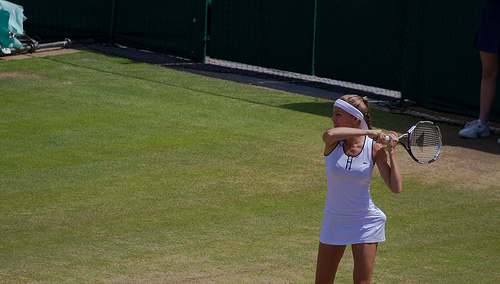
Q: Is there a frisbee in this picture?
A: No, there are no frisbees.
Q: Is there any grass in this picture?
A: Yes, there is grass.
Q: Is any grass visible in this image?
A: Yes, there is grass.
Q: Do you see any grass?
A: Yes, there is grass.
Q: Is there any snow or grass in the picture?
A: Yes, there is grass.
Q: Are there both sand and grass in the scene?
A: No, there is grass but no sand.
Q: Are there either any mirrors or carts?
A: No, there are no carts or mirrors.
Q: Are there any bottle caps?
A: No, there are no bottle caps.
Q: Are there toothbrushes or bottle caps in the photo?
A: No, there are no bottle caps or toothbrushes.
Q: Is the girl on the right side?
A: Yes, the girl is on the right of the image.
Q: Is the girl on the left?
A: No, the girl is on the right of the image.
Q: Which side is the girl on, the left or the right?
A: The girl is on the right of the image.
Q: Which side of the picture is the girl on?
A: The girl is on the right of the image.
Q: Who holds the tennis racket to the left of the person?
A: The girl holds the tennis racket.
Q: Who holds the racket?
A: The girl holds the tennis racket.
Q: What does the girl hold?
A: The girl holds the racket.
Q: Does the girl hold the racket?
A: Yes, the girl holds the racket.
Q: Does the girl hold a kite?
A: No, the girl holds the racket.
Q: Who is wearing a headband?
A: The girl is wearing a headband.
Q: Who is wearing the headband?
A: The girl is wearing a headband.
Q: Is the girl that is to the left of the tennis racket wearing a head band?
A: Yes, the girl is wearing a head band.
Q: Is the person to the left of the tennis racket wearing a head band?
A: Yes, the girl is wearing a head band.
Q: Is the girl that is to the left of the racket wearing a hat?
A: No, the girl is wearing a head band.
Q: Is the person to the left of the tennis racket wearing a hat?
A: No, the girl is wearing a head band.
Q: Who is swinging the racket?
A: The girl is swinging the racket.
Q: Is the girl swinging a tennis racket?
A: Yes, the girl is swinging a tennis racket.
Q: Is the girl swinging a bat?
A: No, the girl is swinging a tennis racket.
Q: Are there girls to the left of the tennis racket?
A: Yes, there is a girl to the left of the tennis racket.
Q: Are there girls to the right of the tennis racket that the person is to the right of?
A: No, the girl is to the left of the tennis racket.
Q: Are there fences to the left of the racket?
A: No, there is a girl to the left of the racket.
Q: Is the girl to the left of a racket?
A: Yes, the girl is to the left of a racket.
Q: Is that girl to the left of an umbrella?
A: No, the girl is to the left of a racket.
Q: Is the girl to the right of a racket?
A: No, the girl is to the left of a racket.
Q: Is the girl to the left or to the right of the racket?
A: The girl is to the left of the racket.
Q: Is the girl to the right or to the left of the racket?
A: The girl is to the left of the racket.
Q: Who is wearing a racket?
A: The girl is wearing a racket.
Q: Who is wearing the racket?
A: The girl is wearing a racket.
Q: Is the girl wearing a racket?
A: Yes, the girl is wearing a racket.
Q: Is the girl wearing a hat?
A: No, the girl is wearing a racket.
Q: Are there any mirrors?
A: No, there are no mirrors.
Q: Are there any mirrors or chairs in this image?
A: No, there are no mirrors or chairs.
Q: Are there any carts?
A: No, there are no carts.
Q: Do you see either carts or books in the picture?
A: No, there are no carts or books.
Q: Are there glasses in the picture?
A: No, there are no glasses.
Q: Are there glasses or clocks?
A: No, there are no glasses or clocks.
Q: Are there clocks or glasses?
A: No, there are no glasses or clocks.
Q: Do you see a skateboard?
A: No, there are no skateboards.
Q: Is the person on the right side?
A: Yes, the person is on the right of the image.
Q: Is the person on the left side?
A: No, the person is on the right of the image.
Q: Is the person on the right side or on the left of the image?
A: The person is on the right of the image.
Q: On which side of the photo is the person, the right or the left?
A: The person is on the right of the image.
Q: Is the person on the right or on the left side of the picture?
A: The person is on the right of the image.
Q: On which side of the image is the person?
A: The person is on the right of the image.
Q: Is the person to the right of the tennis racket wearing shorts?
A: Yes, the person is wearing shorts.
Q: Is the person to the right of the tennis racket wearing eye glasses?
A: No, the person is wearing shorts.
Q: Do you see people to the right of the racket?
A: Yes, there is a person to the right of the racket.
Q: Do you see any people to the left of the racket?
A: No, the person is to the right of the racket.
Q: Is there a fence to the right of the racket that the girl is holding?
A: No, there is a person to the right of the racket.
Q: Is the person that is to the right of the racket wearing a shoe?
A: Yes, the person is wearing a shoe.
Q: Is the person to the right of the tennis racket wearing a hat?
A: No, the person is wearing a shoe.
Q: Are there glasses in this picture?
A: No, there are no glasses.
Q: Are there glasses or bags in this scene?
A: No, there are no glasses or bags.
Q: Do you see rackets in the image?
A: Yes, there is a racket.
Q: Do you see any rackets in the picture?
A: Yes, there is a racket.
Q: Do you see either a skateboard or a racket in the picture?
A: Yes, there is a racket.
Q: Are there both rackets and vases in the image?
A: No, there is a racket but no vases.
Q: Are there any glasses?
A: No, there are no glasses.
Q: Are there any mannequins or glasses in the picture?
A: No, there are no glasses or mannequins.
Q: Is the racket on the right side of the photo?
A: Yes, the racket is on the right of the image.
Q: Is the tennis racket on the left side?
A: No, the tennis racket is on the right of the image.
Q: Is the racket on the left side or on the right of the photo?
A: The racket is on the right of the image.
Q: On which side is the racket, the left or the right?
A: The racket is on the right of the image.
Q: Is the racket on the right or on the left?
A: The racket is on the right of the image.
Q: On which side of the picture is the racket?
A: The racket is on the right of the image.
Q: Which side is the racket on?
A: The racket is on the right of the image.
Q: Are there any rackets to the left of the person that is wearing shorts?
A: Yes, there is a racket to the left of the person.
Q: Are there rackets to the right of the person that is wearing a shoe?
A: No, the racket is to the left of the person.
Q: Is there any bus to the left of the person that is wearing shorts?
A: No, there is a racket to the left of the person.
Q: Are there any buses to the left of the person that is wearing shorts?
A: No, there is a racket to the left of the person.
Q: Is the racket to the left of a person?
A: Yes, the racket is to the left of a person.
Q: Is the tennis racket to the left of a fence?
A: No, the tennis racket is to the left of a person.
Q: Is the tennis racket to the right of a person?
A: No, the tennis racket is to the left of a person.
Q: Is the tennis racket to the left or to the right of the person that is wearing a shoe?
A: The tennis racket is to the left of the person.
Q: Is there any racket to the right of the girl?
A: Yes, there is a racket to the right of the girl.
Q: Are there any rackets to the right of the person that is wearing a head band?
A: Yes, there is a racket to the right of the girl.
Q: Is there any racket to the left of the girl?
A: No, the racket is to the right of the girl.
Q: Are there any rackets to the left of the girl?
A: No, the racket is to the right of the girl.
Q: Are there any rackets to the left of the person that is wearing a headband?
A: No, the racket is to the right of the girl.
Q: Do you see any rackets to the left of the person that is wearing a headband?
A: No, the racket is to the right of the girl.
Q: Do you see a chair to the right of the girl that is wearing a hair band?
A: No, there is a racket to the right of the girl.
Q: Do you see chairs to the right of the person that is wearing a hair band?
A: No, there is a racket to the right of the girl.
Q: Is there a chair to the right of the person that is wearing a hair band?
A: No, there is a racket to the right of the girl.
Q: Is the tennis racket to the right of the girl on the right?
A: Yes, the tennis racket is to the right of the girl.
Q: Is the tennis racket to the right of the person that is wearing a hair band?
A: Yes, the tennis racket is to the right of the girl.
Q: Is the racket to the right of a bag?
A: No, the racket is to the right of the girl.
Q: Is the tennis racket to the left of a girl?
A: No, the tennis racket is to the right of a girl.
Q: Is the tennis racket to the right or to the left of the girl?
A: The tennis racket is to the right of the girl.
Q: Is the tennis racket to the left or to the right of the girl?
A: The tennis racket is to the right of the girl.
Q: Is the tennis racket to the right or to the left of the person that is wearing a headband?
A: The tennis racket is to the right of the girl.